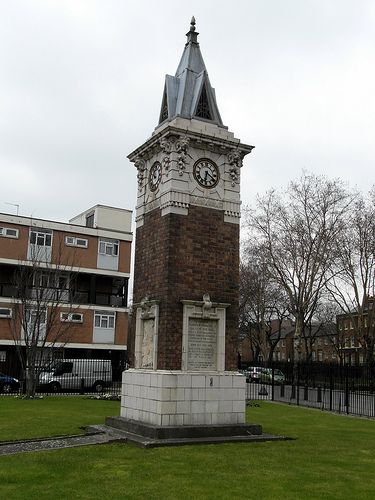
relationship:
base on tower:
[118, 370, 239, 425] [121, 16, 248, 424]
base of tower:
[118, 370, 239, 425] [121, 16, 248, 424]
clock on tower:
[192, 159, 223, 187] [121, 16, 248, 424]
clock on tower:
[147, 161, 166, 192] [121, 16, 248, 424]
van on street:
[51, 355, 114, 393] [5, 367, 122, 398]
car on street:
[5, 368, 23, 392] [5, 367, 122, 398]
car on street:
[259, 366, 287, 387] [249, 381, 373, 424]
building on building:
[0, 202, 133, 394] [4, 209, 125, 395]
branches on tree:
[325, 259, 375, 312] [315, 195, 374, 387]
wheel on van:
[95, 381, 107, 393] [51, 355, 114, 393]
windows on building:
[5, 226, 128, 342] [4, 209, 125, 395]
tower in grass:
[121, 16, 248, 424] [3, 389, 374, 499]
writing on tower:
[190, 320, 217, 369] [121, 16, 248, 424]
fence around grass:
[245, 335, 375, 418] [3, 389, 374, 499]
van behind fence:
[51, 355, 114, 393] [5, 356, 117, 397]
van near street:
[51, 355, 114, 393] [5, 367, 122, 398]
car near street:
[5, 368, 23, 392] [5, 367, 122, 398]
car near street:
[259, 366, 287, 387] [5, 367, 122, 398]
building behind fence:
[4, 209, 125, 395] [5, 356, 117, 397]